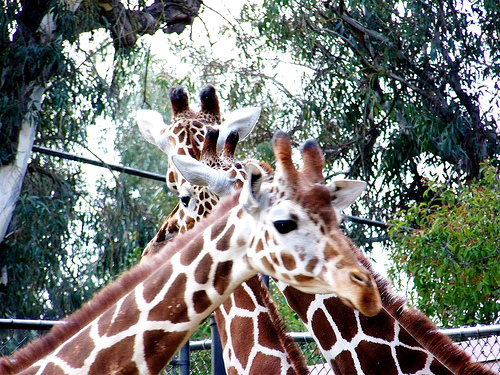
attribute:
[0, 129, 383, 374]
giraffe — standing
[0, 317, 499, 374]
fence — chain linked, chain link, grey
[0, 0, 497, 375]
trees — green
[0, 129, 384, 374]
markings — brown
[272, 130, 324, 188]
horns — black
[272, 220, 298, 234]
eye — black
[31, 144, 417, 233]
bar — metal, black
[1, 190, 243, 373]
mane — short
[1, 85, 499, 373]
giraffes — together